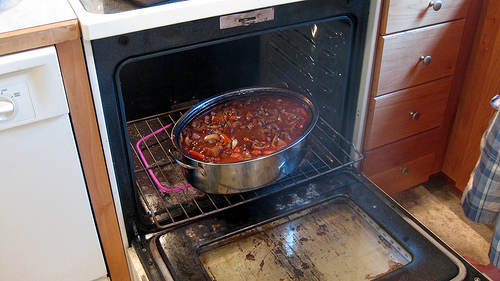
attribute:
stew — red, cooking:
[179, 93, 312, 164]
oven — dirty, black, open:
[114, 17, 481, 279]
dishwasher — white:
[0, 46, 113, 281]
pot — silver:
[169, 87, 318, 194]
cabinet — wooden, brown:
[358, 0, 470, 194]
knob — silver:
[423, 55, 431, 67]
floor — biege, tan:
[387, 180, 494, 266]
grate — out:
[127, 82, 364, 229]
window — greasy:
[196, 198, 414, 279]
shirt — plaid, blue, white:
[463, 85, 498, 264]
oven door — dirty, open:
[127, 165, 493, 280]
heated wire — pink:
[136, 120, 191, 192]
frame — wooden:
[0, 19, 131, 280]